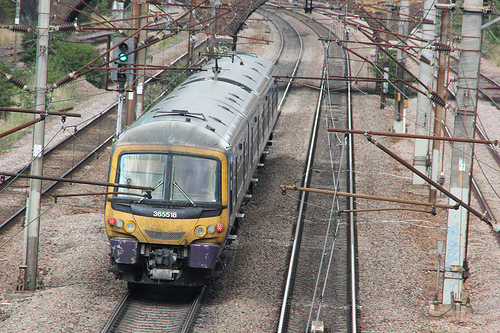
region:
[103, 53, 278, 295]
old train is parked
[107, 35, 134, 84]
light is green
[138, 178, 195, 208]
wind shield wipers on front of train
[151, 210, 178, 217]
white number on front of train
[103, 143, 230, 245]
front of train is yellow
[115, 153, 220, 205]
wind shield on front of train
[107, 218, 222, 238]
head lights on front of train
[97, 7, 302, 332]
train on tracks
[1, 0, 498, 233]
rusted angled poles above train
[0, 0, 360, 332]
empty tracks next to train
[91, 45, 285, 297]
yellow and black train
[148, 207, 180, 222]
number on the front of a train engine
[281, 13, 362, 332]
metal track on the right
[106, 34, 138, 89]
light showing a green light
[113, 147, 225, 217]
windshield in the front of a train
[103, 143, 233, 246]
yellow part on the front of the train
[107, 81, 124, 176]
metal pole holding a traffic light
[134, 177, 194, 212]
windshield wipers on a train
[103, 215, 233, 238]
headlights on the front of the train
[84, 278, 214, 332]
track that the train is on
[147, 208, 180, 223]
the front identification number on a passenger train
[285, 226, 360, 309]
train tracks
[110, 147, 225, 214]
the front windshield of a passenger train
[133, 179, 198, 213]
windshield wipers on a windshield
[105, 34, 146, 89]
a traffic signal in a train yard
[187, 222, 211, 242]
a front headlight on a passenger train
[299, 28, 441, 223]
poles holding electrical wires over a train track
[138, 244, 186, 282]
the front coupling device of a train engine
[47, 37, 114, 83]
some green shrubs near a train track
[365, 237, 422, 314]
small stones next to a train track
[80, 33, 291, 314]
a train on a railroad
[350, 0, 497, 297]
poles with power lines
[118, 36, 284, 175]
roof of train is tan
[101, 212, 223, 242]
headlights in front of train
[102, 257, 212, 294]
bumper of railroad is black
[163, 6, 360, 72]
railroad below powerlines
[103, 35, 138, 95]
traffic light on left side of train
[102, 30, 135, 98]
traffic light in green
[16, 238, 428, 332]
gravel on railroad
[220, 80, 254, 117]
part of a train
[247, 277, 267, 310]
part of a ground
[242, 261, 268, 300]
part of a ground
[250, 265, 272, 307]
part of a ground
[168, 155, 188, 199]
part of a window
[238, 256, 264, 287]
part of a ground